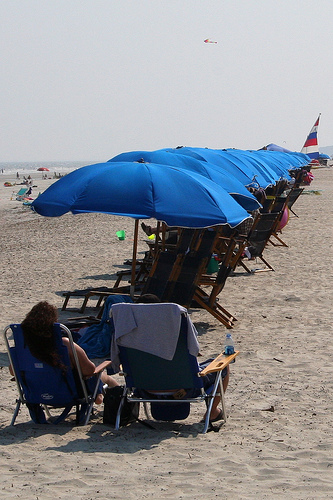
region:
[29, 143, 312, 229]
blue umbrellas lined up in a row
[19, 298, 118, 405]
woman sitting in a beach chair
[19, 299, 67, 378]
woman has long brown hair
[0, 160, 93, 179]
beach is beside the ocean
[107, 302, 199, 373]
gray shirt on back of beach chair,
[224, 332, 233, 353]
water bottle sitting in cup holder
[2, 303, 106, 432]
a person sitting in a beach chair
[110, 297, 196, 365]
a grey shirt hanging over the back of a chair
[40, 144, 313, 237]
several blue open umbrellas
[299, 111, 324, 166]
a red,white and blue sail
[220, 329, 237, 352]
a plastic water bottle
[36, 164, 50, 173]
a red open umbrella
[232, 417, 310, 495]
tracks in the sand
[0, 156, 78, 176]
the ocean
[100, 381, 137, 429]
a black bag on the ground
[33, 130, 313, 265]
umbrellas over the beach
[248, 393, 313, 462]
sand on the ground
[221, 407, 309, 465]
brown sand under people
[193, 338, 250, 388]
arm of the chair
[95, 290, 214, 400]
back of the chair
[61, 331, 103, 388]
arm of the person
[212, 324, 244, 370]
bottle on the chair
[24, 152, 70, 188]
umbrella in the distance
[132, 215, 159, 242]
foot of a person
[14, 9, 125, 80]
The sky is blue in color.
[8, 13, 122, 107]
The sky is clear.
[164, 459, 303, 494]
The sand is light brown in color.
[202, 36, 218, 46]
The plane is in the sky.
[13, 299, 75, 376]
The woman has long hair.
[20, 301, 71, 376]
The woman has brown hair.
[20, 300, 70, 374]
The woman has curly hair.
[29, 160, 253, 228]
The umbrella is blue in color.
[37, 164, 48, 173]
The umbrella is red in color.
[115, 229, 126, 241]
The bucket is green in color.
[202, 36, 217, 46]
colorful kite in the air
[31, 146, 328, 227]
long row of blue umbrellas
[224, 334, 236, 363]
plastic bottle of war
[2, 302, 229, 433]
folding lawn chairs with metal legs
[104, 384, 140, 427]
black bag between chairs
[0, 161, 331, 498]
tan sand on beach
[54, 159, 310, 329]
wooden chairs under umbrellas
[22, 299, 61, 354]
long brunette hair draped on chair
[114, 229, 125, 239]
green bucket in sand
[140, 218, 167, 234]
foot of person under umbrella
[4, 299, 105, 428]
a person sitting in a beach chair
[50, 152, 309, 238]
several blue umbrellas in a row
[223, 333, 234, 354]
a plastic water bottle